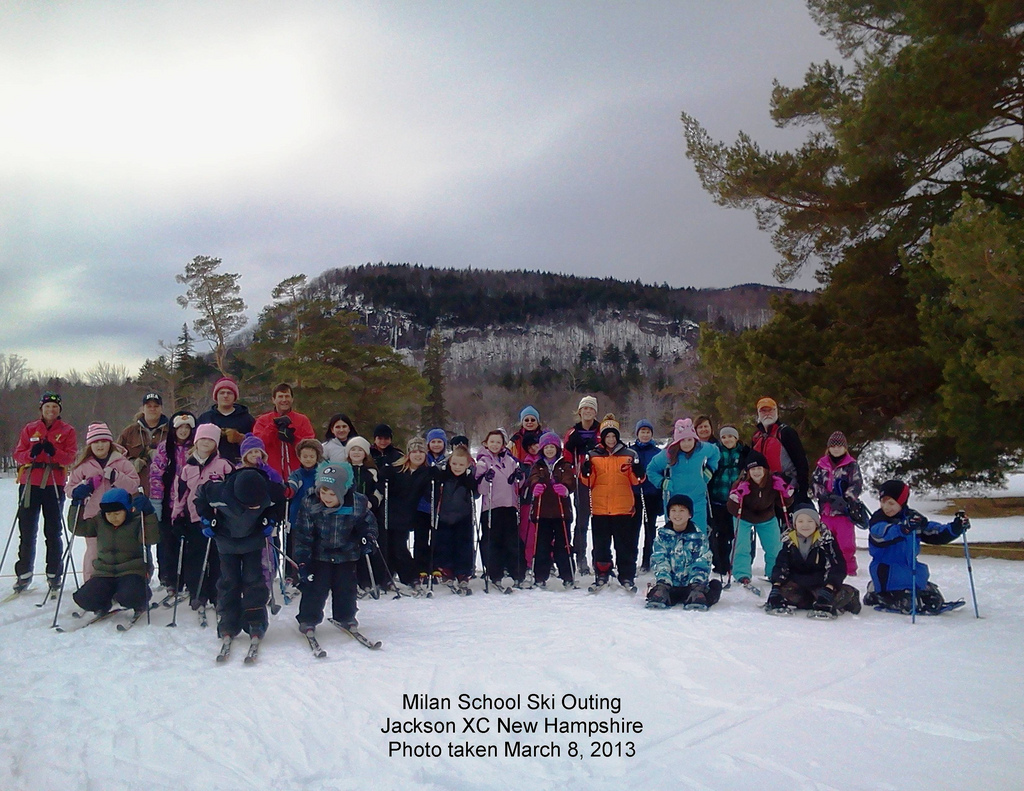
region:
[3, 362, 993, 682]
people is on a snow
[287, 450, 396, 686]
the kid wears a black pants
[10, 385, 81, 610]
the man wears red top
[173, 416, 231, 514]
woman wears pink coat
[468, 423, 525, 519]
woman wears pink coat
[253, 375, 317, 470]
woman wears red coat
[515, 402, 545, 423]
Person wearing blue hat.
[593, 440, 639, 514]
Person wearing orange coat.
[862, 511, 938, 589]
Person wearing blue snow suit.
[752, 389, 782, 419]
Person wearing hat on head.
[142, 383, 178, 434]
Black and white hat on person's face.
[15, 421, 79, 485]
Person wearing red coat.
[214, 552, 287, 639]
Person wearing black pants.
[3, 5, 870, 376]
A blue and white sky.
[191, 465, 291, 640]
Kid in all black bending over with no visible face.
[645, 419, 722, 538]
A girl in all blue with a pink hat on.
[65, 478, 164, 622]
A green coat kid kneeling down with blue hat on.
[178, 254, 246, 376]
A thin tree angled to the left behind people.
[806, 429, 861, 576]
A girl in pink pants and coat with a brown hat.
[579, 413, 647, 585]
Kid in an orange coat in black pants.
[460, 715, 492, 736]
Black XC between Jackson and New.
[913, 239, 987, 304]
green leaves on the tree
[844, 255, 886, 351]
green leaves on the tree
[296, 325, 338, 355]
green leaves on the tree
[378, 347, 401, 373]
green leaves on the tree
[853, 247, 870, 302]
green leaves on the tree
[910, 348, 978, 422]
green leaves on the tree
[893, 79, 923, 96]
green leaves on the tree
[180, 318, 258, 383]
green leaves on the tree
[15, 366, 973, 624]
class picture taken in the snow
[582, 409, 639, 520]
bright orange snow parka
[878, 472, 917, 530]
red stripe on a black hat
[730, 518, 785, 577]
turquoise snow pants on young girl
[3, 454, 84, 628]
ski poles of man in a red jacket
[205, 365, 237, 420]
red hat with a white stripe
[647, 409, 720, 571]
turquoise snow suit with pink hat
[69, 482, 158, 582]
boy wears olive jacket with blue and black hat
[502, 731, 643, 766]
date the picture was taken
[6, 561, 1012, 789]
ski tracks in the snow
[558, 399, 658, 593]
person in orange and black coat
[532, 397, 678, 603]
person in orange and black coat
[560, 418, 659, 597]
person in orange and black coat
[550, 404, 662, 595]
person in orange and black coat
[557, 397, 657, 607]
person in orange and black coat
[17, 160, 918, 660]
people on the snow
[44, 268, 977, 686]
many people standing on the snow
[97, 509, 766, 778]
snow on the ground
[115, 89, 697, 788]
tall trees in the background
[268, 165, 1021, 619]
hills in the background